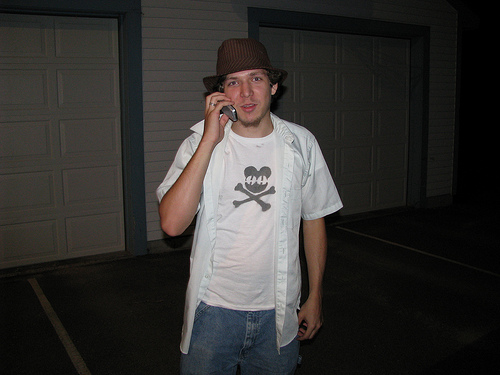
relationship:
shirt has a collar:
[154, 110, 344, 355] [190, 112, 305, 152]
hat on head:
[200, 35, 288, 96] [213, 55, 278, 129]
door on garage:
[255, 23, 416, 224] [1, 5, 498, 374]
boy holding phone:
[153, 37, 331, 370] [207, 89, 239, 123]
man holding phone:
[153, 37, 331, 370] [207, 89, 239, 123]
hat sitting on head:
[200, 35, 288, 96] [213, 55, 278, 129]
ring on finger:
[208, 101, 215, 107] [207, 94, 233, 109]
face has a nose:
[219, 67, 271, 125] [237, 78, 255, 98]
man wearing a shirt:
[153, 37, 331, 370] [154, 110, 344, 355]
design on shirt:
[230, 166, 278, 216] [154, 110, 344, 355]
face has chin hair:
[219, 67, 271, 125] [233, 110, 270, 129]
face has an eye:
[219, 67, 271, 125] [228, 73, 266, 90]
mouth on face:
[239, 99, 260, 113] [219, 67, 271, 125]